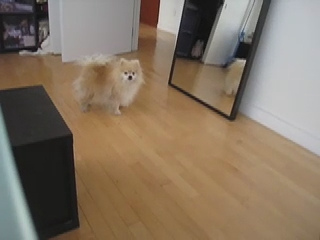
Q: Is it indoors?
A: Yes, it is indoors.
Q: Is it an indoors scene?
A: Yes, it is indoors.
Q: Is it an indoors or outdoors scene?
A: It is indoors.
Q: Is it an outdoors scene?
A: No, it is indoors.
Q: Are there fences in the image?
A: No, there are no fences.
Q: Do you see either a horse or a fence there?
A: No, there are no fences or horses.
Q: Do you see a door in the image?
A: Yes, there is a door.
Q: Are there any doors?
A: Yes, there is a door.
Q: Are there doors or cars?
A: Yes, there is a door.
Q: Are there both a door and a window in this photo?
A: No, there is a door but no windows.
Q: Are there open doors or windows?
A: Yes, there is an open door.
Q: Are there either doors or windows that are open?
A: Yes, the door is open.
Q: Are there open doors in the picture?
A: Yes, there is an open door.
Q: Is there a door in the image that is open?
A: Yes, there is a door that is open.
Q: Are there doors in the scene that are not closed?
A: Yes, there is a open door.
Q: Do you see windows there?
A: No, there are no windows.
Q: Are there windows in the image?
A: No, there are no windows.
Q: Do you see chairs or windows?
A: No, there are no windows or chairs.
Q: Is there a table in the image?
A: No, there are no tables.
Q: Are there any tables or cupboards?
A: No, there are no tables or cupboards.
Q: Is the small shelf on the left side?
A: Yes, the shelf is on the left of the image.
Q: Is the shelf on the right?
A: No, the shelf is on the left of the image.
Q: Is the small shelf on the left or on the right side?
A: The shelf is on the left of the image.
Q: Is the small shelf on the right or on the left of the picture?
A: The shelf is on the left of the image.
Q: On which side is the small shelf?
A: The shelf is on the left of the image.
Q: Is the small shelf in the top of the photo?
A: Yes, the shelf is in the top of the image.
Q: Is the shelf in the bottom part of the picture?
A: No, the shelf is in the top of the image.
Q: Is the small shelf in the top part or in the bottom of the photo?
A: The shelf is in the top of the image.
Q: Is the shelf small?
A: Yes, the shelf is small.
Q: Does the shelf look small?
A: Yes, the shelf is small.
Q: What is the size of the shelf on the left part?
A: The shelf is small.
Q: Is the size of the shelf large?
A: No, the shelf is small.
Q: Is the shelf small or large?
A: The shelf is small.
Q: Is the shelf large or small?
A: The shelf is small.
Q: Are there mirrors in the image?
A: Yes, there is a mirror.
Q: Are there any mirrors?
A: Yes, there is a mirror.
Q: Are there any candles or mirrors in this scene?
A: Yes, there is a mirror.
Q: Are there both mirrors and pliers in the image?
A: No, there is a mirror but no pliers.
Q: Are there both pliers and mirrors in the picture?
A: No, there is a mirror but no pliers.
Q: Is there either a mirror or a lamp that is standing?
A: Yes, the mirror is standing.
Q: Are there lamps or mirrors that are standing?
A: Yes, the mirror is standing.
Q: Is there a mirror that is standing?
A: Yes, there is a mirror that is standing.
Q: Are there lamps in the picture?
A: No, there are no lamps.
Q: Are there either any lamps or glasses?
A: No, there are no lamps or glasses.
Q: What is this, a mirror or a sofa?
A: This is a mirror.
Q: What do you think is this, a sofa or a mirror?
A: This is a mirror.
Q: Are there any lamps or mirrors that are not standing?
A: No, there is a mirror but it is standing.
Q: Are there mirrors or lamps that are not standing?
A: No, there is a mirror but it is standing.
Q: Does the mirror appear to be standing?
A: Yes, the mirror is standing.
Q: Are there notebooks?
A: No, there are no notebooks.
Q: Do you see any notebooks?
A: No, there are no notebooks.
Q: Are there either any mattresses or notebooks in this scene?
A: No, there are no notebooks or mattresses.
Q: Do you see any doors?
A: Yes, there is a door.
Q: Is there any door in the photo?
A: Yes, there is a door.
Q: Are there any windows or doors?
A: Yes, there is a door.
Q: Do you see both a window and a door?
A: No, there is a door but no windows.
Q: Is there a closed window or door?
A: Yes, there is a closed door.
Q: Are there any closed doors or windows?
A: Yes, there is a closed door.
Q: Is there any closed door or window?
A: Yes, there is a closed door.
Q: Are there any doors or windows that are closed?
A: Yes, the door is closed.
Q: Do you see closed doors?
A: Yes, there is a closed door.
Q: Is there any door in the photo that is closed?
A: Yes, there is a door that is closed.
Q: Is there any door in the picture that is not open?
A: Yes, there is an closed door.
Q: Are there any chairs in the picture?
A: No, there are no chairs.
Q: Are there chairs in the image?
A: No, there are no chairs.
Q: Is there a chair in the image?
A: No, there are no chairs.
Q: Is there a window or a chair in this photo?
A: No, there are no chairs or windows.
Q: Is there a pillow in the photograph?
A: No, there are no pillows.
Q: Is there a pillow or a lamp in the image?
A: No, there are no pillows or lamps.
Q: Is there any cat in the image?
A: Yes, there is a cat.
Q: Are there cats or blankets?
A: Yes, there is a cat.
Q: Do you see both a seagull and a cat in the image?
A: No, there is a cat but no seagulls.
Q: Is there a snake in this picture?
A: No, there are no snakes.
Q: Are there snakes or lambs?
A: No, there are no snakes or lambs.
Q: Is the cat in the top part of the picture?
A: Yes, the cat is in the top of the image.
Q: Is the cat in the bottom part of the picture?
A: No, the cat is in the top of the image.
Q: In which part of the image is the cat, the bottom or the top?
A: The cat is in the top of the image.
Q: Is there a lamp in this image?
A: No, there are no lamps.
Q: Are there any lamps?
A: No, there are no lamps.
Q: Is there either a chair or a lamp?
A: No, there are no lamps or chairs.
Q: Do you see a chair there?
A: No, there are no chairs.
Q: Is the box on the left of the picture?
A: Yes, the box is on the left of the image.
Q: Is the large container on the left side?
A: Yes, the box is on the left of the image.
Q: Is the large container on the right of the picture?
A: No, the box is on the left of the image.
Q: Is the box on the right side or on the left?
A: The box is on the left of the image.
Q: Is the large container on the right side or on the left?
A: The box is on the left of the image.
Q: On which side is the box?
A: The box is on the left of the image.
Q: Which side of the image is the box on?
A: The box is on the left of the image.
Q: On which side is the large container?
A: The box is on the left of the image.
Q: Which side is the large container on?
A: The box is on the left of the image.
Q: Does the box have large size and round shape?
A: No, the box is large but square.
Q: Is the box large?
A: Yes, the box is large.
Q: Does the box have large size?
A: Yes, the box is large.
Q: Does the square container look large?
A: Yes, the box is large.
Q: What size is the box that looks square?
A: The box is large.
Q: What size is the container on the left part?
A: The box is large.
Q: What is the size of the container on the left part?
A: The box is large.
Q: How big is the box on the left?
A: The box is large.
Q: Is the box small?
A: No, the box is large.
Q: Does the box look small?
A: No, the box is large.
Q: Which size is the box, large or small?
A: The box is large.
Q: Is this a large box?
A: Yes, this is a large box.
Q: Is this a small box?
A: No, this is a large box.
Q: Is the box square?
A: Yes, the box is square.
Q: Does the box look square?
A: Yes, the box is square.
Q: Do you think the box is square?
A: Yes, the box is square.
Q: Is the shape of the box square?
A: Yes, the box is square.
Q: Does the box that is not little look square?
A: Yes, the box is square.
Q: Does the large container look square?
A: Yes, the box is square.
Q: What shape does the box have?
A: The box has square shape.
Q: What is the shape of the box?
A: The box is square.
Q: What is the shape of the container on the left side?
A: The box is square.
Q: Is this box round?
A: No, the box is square.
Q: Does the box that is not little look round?
A: No, the box is square.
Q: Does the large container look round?
A: No, the box is square.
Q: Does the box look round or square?
A: The box is square.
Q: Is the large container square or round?
A: The box is square.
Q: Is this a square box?
A: Yes, this is a square box.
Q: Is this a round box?
A: No, this is a square box.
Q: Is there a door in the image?
A: Yes, there is a door.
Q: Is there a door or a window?
A: Yes, there is a door.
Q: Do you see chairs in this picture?
A: No, there are no chairs.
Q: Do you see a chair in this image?
A: No, there are no chairs.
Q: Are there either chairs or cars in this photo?
A: No, there are no chairs or cars.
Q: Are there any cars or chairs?
A: No, there are no chairs or cars.